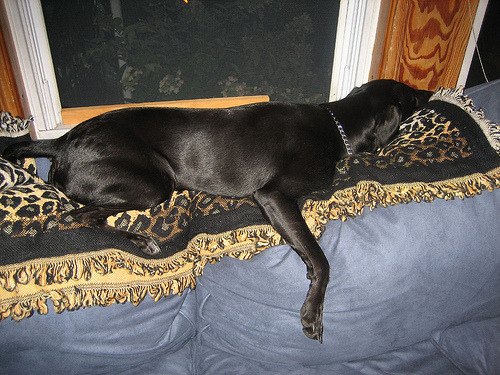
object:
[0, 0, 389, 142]
window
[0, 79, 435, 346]
dog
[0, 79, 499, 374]
fabric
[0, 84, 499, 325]
blanket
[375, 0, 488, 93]
wall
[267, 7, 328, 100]
plant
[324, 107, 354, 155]
chain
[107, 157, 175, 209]
leg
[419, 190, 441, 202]
tassles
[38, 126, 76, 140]
sill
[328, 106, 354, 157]
collar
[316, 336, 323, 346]
claws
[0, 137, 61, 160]
tail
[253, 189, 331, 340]
arm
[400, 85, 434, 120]
face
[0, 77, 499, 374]
couch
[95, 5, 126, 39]
leaves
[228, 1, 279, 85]
tree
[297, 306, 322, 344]
paw